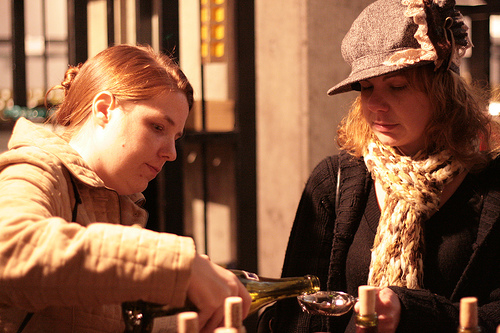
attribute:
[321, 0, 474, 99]
hat — brown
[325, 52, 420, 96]
brim — large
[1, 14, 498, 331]
women — young, warmly dressed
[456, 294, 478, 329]
cork — wine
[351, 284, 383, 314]
cork — wine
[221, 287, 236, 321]
cork — wine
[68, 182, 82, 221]
strap — black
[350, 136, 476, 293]
scarf — loosely knit, muted tone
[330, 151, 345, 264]
strap — black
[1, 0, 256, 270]
doors — black, wood, glass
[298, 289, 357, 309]
bowl — small, silver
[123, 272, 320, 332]
bottle — green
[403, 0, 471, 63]
decoration — lace